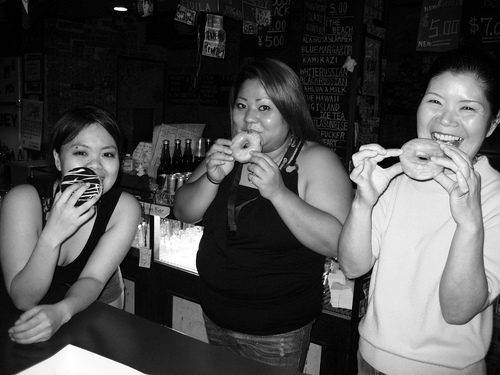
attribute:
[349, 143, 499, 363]
sweatshirt — white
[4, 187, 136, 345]
top — black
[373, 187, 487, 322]
shirt — white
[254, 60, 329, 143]
hair — long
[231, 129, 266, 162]
donut — plain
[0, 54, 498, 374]
ladies — three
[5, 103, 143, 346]
woman — Asian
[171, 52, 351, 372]
woman — Asian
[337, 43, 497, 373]
woman — Asian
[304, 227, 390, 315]
elbow — bent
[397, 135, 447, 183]
donut — glazed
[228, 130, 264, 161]
donut — glazed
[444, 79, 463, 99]
lay — light skinned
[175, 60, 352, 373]
lady — fat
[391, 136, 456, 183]
donut — plain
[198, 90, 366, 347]
lady — eating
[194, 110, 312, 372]
blouse — black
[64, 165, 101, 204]
donut — brown, white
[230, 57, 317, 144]
hair — long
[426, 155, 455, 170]
fingers — slim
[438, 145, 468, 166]
fingers — slim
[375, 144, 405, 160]
fingers — slim